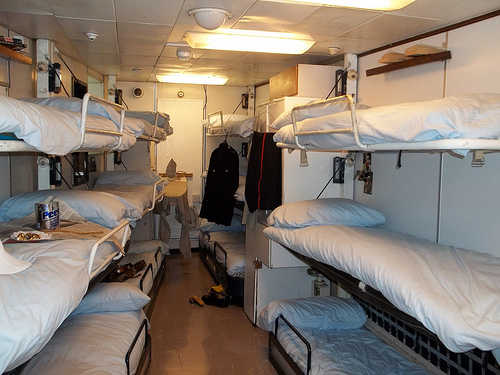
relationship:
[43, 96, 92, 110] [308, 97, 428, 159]
pillow on bed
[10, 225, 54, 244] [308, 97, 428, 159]
food on top of bed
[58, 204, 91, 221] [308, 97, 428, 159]
newspaper on top of bed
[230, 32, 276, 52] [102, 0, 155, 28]
lighting on ceiling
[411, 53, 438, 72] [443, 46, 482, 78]
shelf hanging on wall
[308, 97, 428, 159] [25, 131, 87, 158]
bed on board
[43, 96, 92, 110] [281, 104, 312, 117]
pillow inside pillowcase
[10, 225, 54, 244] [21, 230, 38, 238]
food on plate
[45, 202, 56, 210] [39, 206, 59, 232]
drink inside carton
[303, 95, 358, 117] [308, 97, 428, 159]
arm attached to bed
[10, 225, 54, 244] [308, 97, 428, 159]
food on bed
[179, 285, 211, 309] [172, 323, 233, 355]
boots are on floor